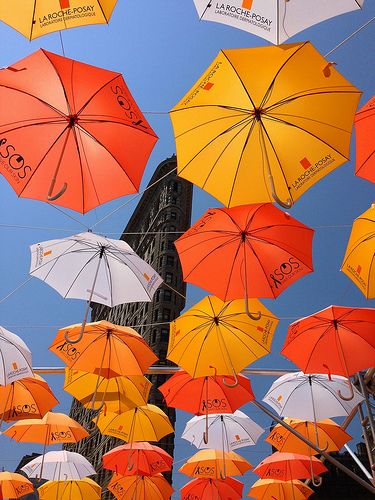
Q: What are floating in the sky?
A: Umbrellas.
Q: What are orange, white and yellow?
A: Umbrellas.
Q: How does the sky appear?
A: Crisp and blue.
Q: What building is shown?
A: A stone building.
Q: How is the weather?
A: Clear and sunny.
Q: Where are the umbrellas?
A: In the air.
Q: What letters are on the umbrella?
A: SOS.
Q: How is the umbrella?
A: Open.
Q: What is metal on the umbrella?
A: Wires.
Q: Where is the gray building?
A: Behind the umbrellas.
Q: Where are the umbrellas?
A: In front of the building.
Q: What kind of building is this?
A: Flat iron.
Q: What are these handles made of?
A: Wood.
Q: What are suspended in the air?
A: Umbrellas.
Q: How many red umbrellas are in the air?
A: Eight.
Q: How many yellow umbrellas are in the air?
A: Seven.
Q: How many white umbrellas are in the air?
A: Six.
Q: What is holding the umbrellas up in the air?
A: Wires.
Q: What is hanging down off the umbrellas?
A: Handles.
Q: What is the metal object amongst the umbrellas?
A: A metal Bar.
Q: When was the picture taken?
A: Daytime.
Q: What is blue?
A: Sky.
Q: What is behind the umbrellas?
A: Building.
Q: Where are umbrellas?
A: In the air.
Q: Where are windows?
A: On a building.